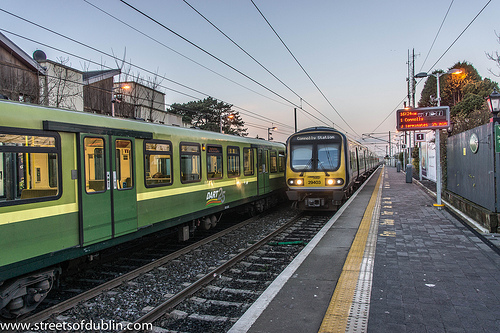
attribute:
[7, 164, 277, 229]
stripe — yellow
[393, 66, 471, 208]
light — tall, outdoor, street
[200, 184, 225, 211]
name — train company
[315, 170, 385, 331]
stripe — yellow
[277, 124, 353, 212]
engine — yellow, train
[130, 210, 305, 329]
tracks — set, train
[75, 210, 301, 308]
tracks — train, set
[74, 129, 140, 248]
doors — set, green, train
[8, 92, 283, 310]
car — train, green, passenger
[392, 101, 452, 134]
board — electronic, sign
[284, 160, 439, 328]
platform — passenger, train, boarding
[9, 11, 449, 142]
lines — overhead, power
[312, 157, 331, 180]
wiper — train, windshield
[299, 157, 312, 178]
wiper — windshield, train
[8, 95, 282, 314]
train — green, passenger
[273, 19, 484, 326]
train — yellow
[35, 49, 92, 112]
house — second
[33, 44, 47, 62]
dish — satelite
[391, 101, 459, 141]
sign — lighted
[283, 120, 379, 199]
train — yellow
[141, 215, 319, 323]
tracks — train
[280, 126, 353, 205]
train — yellow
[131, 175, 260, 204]
line — yellow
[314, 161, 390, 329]
line — yellow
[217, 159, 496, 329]
platform — train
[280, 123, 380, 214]
train — long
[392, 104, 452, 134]
sign — digital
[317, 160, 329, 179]
wiper — windshield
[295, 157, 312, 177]
wiper — windshield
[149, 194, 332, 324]
tracks — brown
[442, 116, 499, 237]
fence — gray